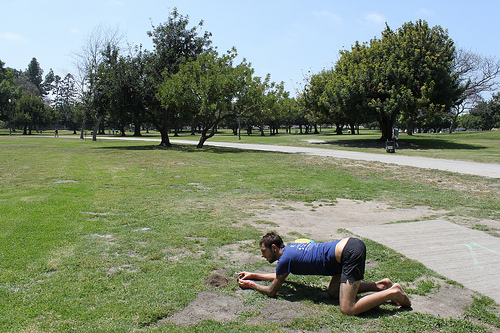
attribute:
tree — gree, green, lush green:
[157, 46, 293, 149]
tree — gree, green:
[313, 20, 471, 145]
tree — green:
[130, 6, 215, 148]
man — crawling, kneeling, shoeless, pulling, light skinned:
[235, 232, 415, 314]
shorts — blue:
[341, 235, 366, 285]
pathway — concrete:
[6, 131, 500, 181]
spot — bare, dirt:
[242, 194, 458, 243]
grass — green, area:
[0, 134, 499, 333]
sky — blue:
[1, 1, 498, 118]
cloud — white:
[363, 10, 385, 27]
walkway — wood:
[342, 217, 500, 305]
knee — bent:
[336, 303, 361, 318]